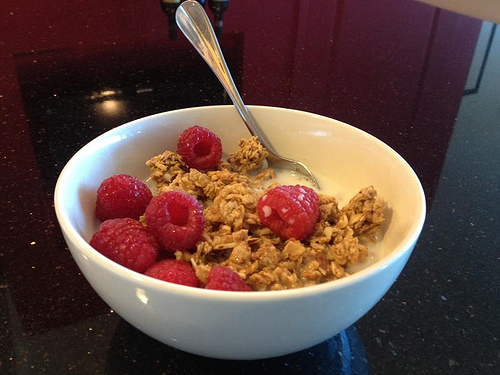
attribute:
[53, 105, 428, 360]
bowl — white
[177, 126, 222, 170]
raspberry — red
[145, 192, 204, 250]
raspberry — red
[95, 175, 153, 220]
raspberry — red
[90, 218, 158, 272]
raspberry — red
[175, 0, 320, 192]
spoon — silver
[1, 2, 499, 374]
counter — black, granite